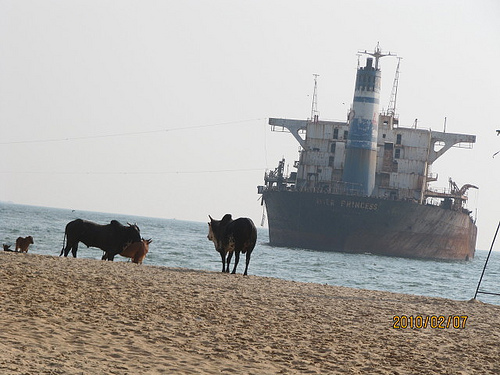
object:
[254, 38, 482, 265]
ship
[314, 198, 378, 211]
name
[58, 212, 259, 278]
group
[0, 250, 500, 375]
beach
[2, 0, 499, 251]
sky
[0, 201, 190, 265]
water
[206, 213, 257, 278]
bull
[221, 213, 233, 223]
hump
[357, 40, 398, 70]
antenna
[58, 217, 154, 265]
animal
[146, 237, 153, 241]
horns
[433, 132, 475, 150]
railing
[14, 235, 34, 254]
animal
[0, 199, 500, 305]
ocean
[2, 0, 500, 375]
picture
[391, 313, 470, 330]
date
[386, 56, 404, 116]
rig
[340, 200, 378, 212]
princess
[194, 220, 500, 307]
water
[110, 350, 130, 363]
footprints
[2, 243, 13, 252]
cow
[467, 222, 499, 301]
something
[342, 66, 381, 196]
pipe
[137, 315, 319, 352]
sand